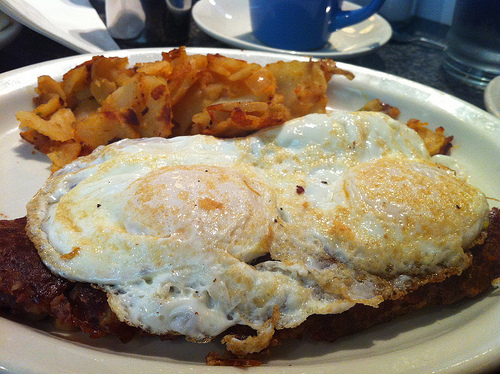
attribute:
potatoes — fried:
[58, 63, 322, 130]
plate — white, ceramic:
[0, 43, 493, 372]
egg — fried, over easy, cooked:
[266, 130, 489, 289]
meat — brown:
[2, 225, 493, 324]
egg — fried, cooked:
[37, 161, 267, 288]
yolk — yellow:
[335, 163, 465, 251]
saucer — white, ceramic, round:
[189, 1, 415, 56]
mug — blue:
[251, 0, 392, 45]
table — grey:
[17, 14, 500, 79]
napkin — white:
[13, 4, 143, 52]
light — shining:
[355, 19, 381, 41]